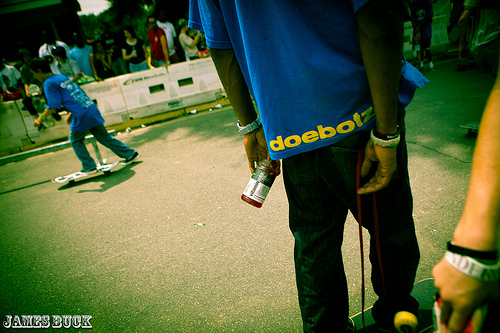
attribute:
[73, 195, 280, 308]
concrete — grey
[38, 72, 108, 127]
shirt — blue 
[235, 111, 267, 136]
watch — white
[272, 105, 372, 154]
letters — yellow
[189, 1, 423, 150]
shirt — blue 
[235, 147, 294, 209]
bottle — drink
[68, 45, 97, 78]
shirt — light, blue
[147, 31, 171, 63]
shirt — red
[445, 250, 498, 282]
lettering — black 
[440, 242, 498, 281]
wristband — white 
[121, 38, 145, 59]
shirt — black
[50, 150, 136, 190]
skateboard — white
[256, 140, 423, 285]
jeans — blue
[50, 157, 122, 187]
skate board — white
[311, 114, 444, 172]
bracelets — black, white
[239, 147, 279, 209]
bottle — clear, plastic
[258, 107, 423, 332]
pants — blue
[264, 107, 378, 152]
lettering — yellow 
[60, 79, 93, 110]
lettering — white 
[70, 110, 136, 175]
jeans — blue 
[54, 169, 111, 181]
squares — black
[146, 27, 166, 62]
shirt — red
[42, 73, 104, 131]
shirt — blue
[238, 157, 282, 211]
drink — red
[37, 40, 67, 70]
shirt — white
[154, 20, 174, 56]
shirt — white